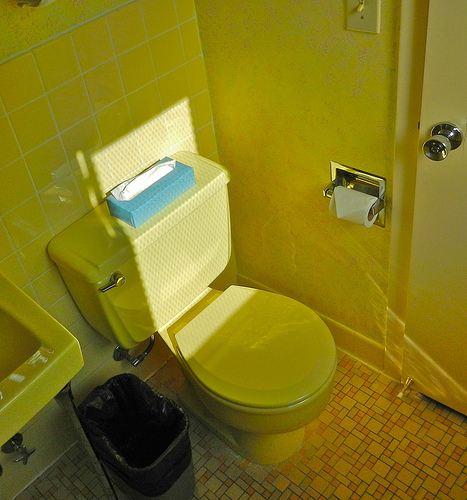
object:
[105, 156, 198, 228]
box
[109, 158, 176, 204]
kleenex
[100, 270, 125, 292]
lever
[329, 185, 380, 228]
toilet paper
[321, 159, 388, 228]
dispenser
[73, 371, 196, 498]
garbage can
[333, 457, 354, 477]
tile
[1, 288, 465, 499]
floor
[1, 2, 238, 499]
wall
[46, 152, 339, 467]
toilet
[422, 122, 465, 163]
handle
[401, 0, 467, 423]
door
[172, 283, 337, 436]
toilet seat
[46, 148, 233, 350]
toilet tank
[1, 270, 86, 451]
sink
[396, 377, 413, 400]
door stopper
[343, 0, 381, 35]
light switch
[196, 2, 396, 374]
wall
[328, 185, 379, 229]
roll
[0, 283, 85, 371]
edge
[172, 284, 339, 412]
cover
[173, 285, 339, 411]
toilet lid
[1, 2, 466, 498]
photo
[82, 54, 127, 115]
tile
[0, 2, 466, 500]
bathroom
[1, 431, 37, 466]
tap